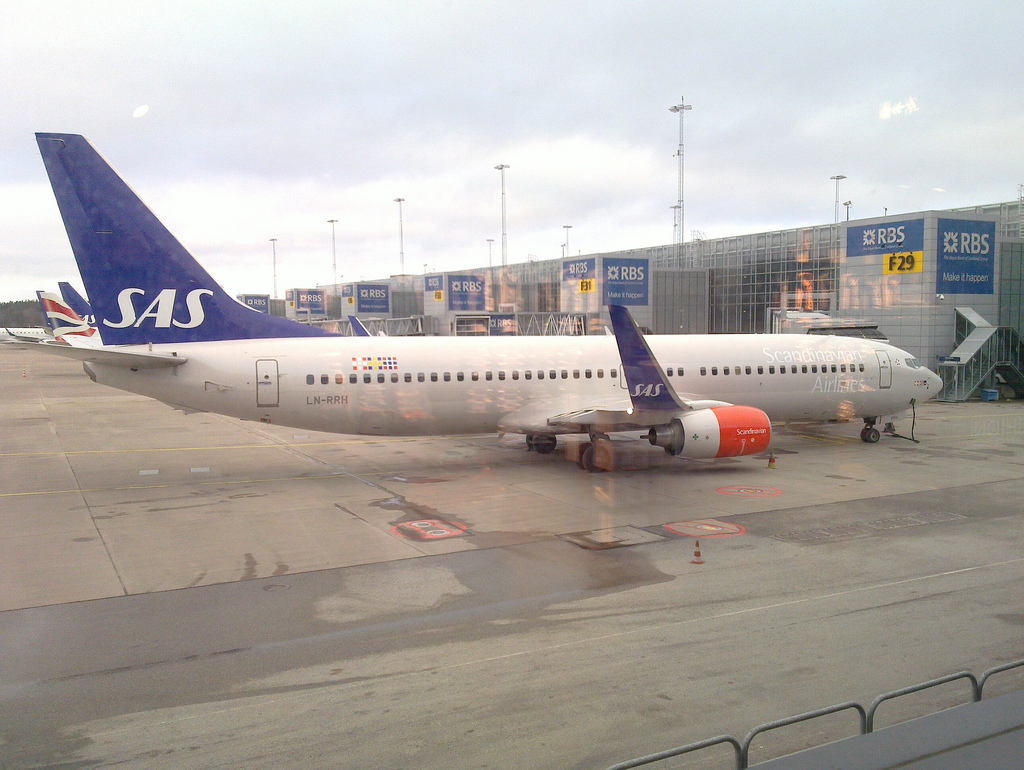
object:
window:
[306, 374, 315, 385]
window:
[417, 372, 426, 381]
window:
[611, 368, 617, 377]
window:
[443, 371, 452, 382]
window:
[499, 370, 505, 381]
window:
[559, 368, 567, 377]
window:
[485, 371, 493, 380]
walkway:
[725, 684, 1024, 770]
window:
[391, 373, 400, 384]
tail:
[24, 124, 237, 329]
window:
[473, 371, 482, 382]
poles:
[487, 238, 495, 266]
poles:
[669, 94, 693, 241]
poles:
[829, 174, 846, 223]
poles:
[394, 197, 405, 274]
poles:
[269, 236, 278, 298]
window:
[514, 370, 522, 381]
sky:
[0, 0, 1024, 303]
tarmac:
[0, 321, 1024, 770]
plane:
[28, 126, 942, 471]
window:
[859, 365, 867, 372]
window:
[321, 373, 330, 385]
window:
[403, 372, 412, 383]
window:
[417, 373, 426, 384]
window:
[430, 372, 438, 381]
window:
[457, 371, 466, 380]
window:
[525, 370, 534, 379]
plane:
[0, 319, 54, 343]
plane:
[56, 279, 95, 325]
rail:
[600, 665, 1016, 770]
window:
[512, 372, 520, 381]